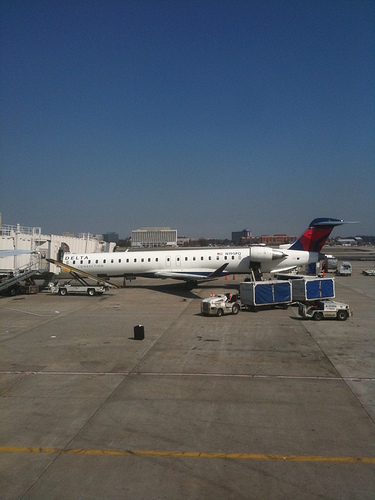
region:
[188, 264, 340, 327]
a luggage loading cart.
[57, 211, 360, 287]
a passenger jet on a tarmac.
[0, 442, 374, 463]
a yellow line on a tarmac.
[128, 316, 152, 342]
a container on a tarmac.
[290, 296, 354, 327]
a small vehicle.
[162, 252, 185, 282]
loading side of a plane.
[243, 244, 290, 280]
a jet engine on a jetliner.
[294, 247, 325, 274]
a jet engine on the back of a plain.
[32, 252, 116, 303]
a loading vehicle near a plane.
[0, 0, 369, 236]
a dark blue sky.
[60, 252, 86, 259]
"DELTA" painted on the side of a jet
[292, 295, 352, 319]
a 'TUG' ground support tractor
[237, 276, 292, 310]
a closed baggage cart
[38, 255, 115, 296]
a baggage loader with loader extended in 'up' position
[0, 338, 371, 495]
a section of the the airport ramp tarmac area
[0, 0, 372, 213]
a blue sky in the background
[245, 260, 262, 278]
a baggage loader extended into the port aft cargo compartment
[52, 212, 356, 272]
a narrow body DELTA Airlines jet at a jetway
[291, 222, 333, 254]
DELTA Airlines tail logo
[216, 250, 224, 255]
an American flag painted on the side of the jet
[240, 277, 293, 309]
the grey and blue luggage car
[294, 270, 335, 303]
the grey and blue luggage car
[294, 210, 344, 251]
the blue and red plane tail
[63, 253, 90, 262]
the delta logo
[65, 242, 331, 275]
the long body of a plane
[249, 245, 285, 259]
the engine of a plane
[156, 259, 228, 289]
the wing of a plane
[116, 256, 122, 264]
the window of a plane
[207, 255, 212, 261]
the window of a plane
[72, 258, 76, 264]
the window of a plane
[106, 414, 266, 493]
A yellow line is visible.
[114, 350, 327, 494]
A yellow line is visible.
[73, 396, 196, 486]
A yellow line is visible.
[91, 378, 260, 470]
A yellow line is visible.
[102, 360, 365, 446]
tje runway is gray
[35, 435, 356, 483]
the stripe is long and yellow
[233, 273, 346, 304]
the luggage cart is blue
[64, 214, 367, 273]
the airplane is red white and blue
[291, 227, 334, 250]
the airplane has a logo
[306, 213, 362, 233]
the horizontal stabilizer is blue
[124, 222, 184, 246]
a building behind the plane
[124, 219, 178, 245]
the building is wide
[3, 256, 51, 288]
the ramp is steep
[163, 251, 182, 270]
the airplane has doors